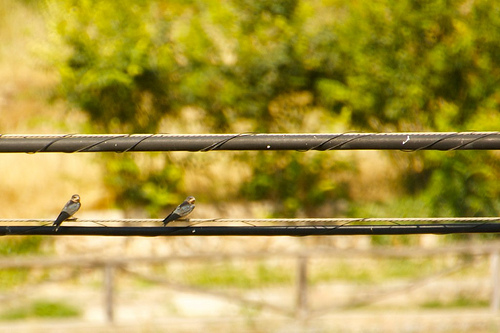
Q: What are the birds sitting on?
A: A wire.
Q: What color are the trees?
A: Green.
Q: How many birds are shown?
A: 2.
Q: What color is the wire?
A: Black.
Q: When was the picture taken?
A: Daylight.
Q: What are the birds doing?
A: Sitting on a wire.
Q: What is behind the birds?
A: A fence.